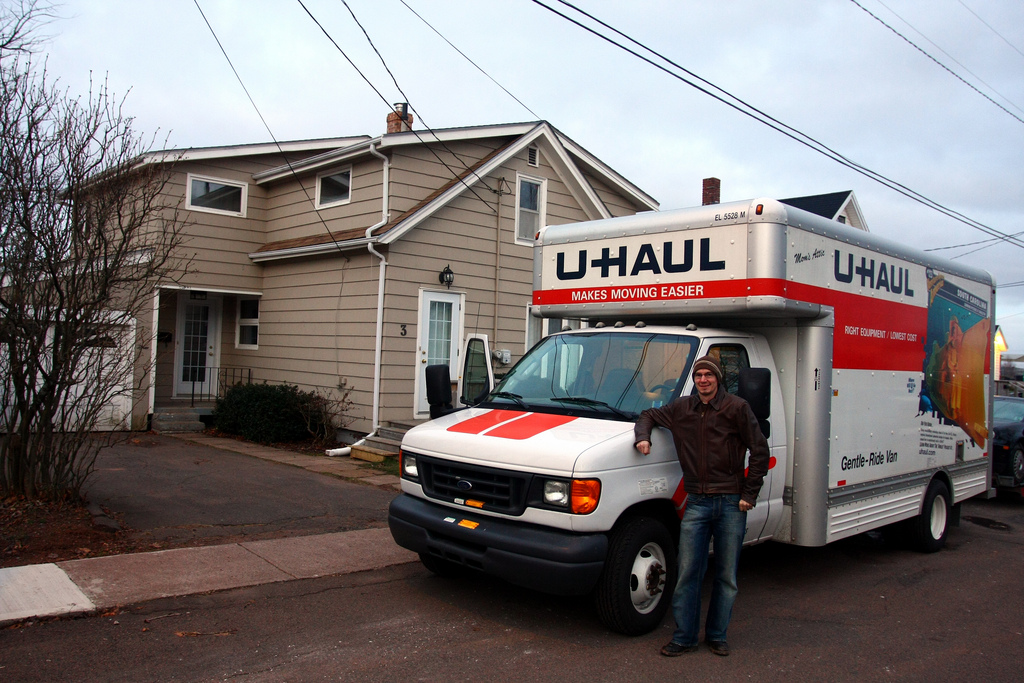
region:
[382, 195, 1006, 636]
A u haul truck parked along a curb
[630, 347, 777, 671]
a man leaning against a truck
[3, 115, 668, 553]
A house with light brown siding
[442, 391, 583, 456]
orange stripes on the hood of a truck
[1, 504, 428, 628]
a sidewalk runs in front of the house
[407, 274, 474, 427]
a glass door with white trim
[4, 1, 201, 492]
a leafless tree in front of a house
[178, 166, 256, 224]
a window with white trim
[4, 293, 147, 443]
a white garage door visible behind a tree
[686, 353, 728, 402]
a man is weearing a knit cap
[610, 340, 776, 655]
Man is wearing blue jeans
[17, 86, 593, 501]
House is brown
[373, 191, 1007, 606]
Man is leaning on uHaul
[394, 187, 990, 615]
uHaul has red stripe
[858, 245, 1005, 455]
uHaul has picture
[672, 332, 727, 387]
Man is wearing hat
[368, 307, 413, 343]
House is number 3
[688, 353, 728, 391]
Person wearing hat on head.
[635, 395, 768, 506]
Person wearing brown jacket.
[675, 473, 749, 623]
Person wearing blue jeans.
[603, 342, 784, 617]
Person standing in front of uhaul.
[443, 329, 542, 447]
Door on uhaul is open.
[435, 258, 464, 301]
Light above door on house.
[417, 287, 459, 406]
White door on brown house.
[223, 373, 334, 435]
Green bush in front of house.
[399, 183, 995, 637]
A moving truck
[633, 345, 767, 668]
A man is leaning on the truck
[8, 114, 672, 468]
A house by the road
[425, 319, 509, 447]
The door to the truck is open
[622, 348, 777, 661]
the man is wearing a winter coat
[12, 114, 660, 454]
the house is tan with white trim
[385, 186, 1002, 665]
A man posing with a moving truck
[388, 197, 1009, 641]
The truck is in a residential neighborhood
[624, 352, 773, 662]
Guy in blue jeans smiling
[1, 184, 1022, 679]
U-Haul trunk on the side of the road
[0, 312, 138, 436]
White garage door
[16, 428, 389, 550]
Asphalt driveway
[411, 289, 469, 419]
White entry door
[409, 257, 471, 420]
Black light above the door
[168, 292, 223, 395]
White entry door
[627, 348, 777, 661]
Guy in blue jeans wearing leather jacket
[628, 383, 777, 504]
Brown leather jacket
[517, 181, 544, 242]
Window of a house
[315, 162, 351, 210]
Window of a house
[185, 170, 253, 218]
Window of a house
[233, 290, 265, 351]
Window of a house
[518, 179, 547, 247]
Window of a tan house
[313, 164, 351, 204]
Window of a tan house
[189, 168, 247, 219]
Window of a tan house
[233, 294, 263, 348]
Window of a tan house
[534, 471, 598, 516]
Headlight of a vehicle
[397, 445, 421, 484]
Headlight of a vehicle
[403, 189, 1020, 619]
white and orange moving truck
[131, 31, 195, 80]
white clouds in blue sky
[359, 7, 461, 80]
white clouds in blue sky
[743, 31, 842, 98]
white clouds in blue sky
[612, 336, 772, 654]
the man is leaning on the truck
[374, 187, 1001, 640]
the truck is a uhaul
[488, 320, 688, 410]
the windshield of the truck